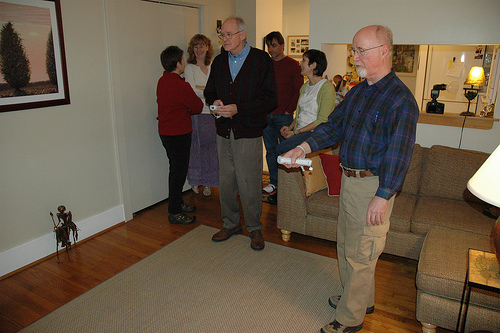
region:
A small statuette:
[47, 202, 99, 261]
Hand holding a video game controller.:
[272, 147, 331, 174]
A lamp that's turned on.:
[457, 59, 488, 120]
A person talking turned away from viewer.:
[152, 43, 204, 230]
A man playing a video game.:
[200, 17, 278, 257]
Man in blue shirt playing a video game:
[271, 24, 431, 331]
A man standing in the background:
[261, 22, 309, 200]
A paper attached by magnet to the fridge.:
[445, 54, 464, 81]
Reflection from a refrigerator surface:
[457, 50, 468, 65]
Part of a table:
[453, 243, 498, 330]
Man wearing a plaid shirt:
[287, 24, 419, 331]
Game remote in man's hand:
[275, 148, 315, 177]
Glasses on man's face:
[347, 42, 387, 57]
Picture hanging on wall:
[0, 10, 75, 113]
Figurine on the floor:
[37, 199, 85, 260]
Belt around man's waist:
[327, 160, 378, 185]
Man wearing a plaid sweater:
[200, 16, 277, 250]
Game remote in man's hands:
[208, 98, 227, 119]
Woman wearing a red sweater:
[139, 46, 204, 228]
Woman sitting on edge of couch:
[267, 47, 337, 164]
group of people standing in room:
[134, 0, 414, 317]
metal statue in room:
[44, 205, 82, 260]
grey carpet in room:
[137, 228, 219, 331]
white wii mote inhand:
[272, 150, 322, 167]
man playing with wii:
[248, 18, 412, 326]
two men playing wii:
[200, 5, 423, 331]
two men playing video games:
[174, 14, 406, 331]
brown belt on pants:
[337, 171, 371, 183]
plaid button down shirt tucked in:
[309, 79, 415, 176]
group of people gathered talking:
[155, 32, 312, 150]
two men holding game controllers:
[203, 23, 398, 187]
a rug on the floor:
[83, 241, 290, 330]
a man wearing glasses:
[352, 25, 400, 76]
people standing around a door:
[157, 13, 299, 117]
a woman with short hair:
[297, 46, 325, 86]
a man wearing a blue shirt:
[209, 42, 268, 115]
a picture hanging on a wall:
[5, 6, 79, 114]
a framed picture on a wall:
[25, 22, 92, 116]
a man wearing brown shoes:
[201, 228, 278, 250]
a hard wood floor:
[77, 219, 164, 281]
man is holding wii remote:
[269, 13, 421, 331]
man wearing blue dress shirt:
[291, 72, 426, 205]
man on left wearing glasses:
[346, 40, 391, 57]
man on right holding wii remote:
[189, 11, 285, 253]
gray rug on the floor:
[16, 216, 353, 330]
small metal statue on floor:
[44, 195, 85, 265]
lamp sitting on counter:
[462, 60, 490, 126]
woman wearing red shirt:
[146, 39, 210, 234]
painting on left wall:
[1, 0, 73, 119]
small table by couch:
[443, 243, 498, 332]